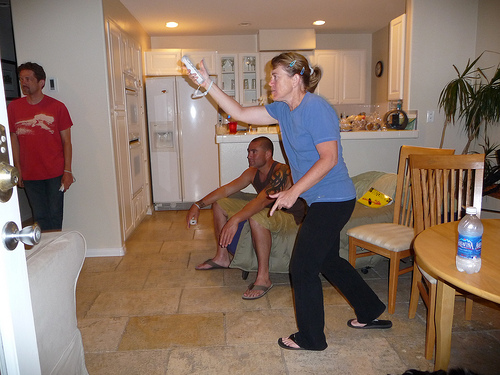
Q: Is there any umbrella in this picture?
A: No, there are no umbrellas.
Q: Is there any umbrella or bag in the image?
A: No, there are no umbrellas or bags.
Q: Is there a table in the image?
A: Yes, there is a table.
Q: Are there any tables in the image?
A: Yes, there is a table.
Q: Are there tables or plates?
A: Yes, there is a table.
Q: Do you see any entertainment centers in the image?
A: No, there are no entertainment centers.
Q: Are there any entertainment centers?
A: No, there are no entertainment centers.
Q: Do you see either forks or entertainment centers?
A: No, there are no entertainment centers or forks.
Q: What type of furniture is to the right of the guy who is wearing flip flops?
A: The piece of furniture is a table.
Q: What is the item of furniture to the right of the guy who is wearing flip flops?
A: The piece of furniture is a table.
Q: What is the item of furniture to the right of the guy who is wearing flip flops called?
A: The piece of furniture is a table.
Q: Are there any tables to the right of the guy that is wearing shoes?
A: Yes, there is a table to the right of the guy.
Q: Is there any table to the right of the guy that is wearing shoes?
A: Yes, there is a table to the right of the guy.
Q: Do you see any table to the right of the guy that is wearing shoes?
A: Yes, there is a table to the right of the guy.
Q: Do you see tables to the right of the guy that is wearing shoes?
A: Yes, there is a table to the right of the guy.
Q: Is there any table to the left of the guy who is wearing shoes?
A: No, the table is to the right of the guy.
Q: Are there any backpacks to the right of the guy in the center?
A: No, there is a table to the right of the guy.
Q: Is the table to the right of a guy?
A: Yes, the table is to the right of a guy.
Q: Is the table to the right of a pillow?
A: No, the table is to the right of a guy.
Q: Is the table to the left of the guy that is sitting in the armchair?
A: No, the table is to the right of the guy.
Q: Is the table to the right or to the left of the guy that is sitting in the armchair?
A: The table is to the right of the guy.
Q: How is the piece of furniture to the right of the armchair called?
A: The piece of furniture is a table.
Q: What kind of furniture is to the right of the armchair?
A: The piece of furniture is a table.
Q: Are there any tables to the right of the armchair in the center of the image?
A: Yes, there is a table to the right of the armchair.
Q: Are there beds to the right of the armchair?
A: No, there is a table to the right of the armchair.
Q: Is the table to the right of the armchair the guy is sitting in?
A: Yes, the table is to the right of the armchair.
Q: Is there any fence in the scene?
A: No, there are no fences.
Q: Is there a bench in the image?
A: No, there are no benches.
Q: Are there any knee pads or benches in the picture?
A: No, there are no benches or knee pads.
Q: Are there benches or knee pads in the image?
A: No, there are no benches or knee pads.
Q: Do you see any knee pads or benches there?
A: No, there are no benches or knee pads.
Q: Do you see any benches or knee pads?
A: No, there are no benches or knee pads.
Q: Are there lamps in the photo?
A: No, there are no lamps.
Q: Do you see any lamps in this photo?
A: No, there are no lamps.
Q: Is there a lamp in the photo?
A: No, there are no lamps.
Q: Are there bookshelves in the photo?
A: No, there are no bookshelves.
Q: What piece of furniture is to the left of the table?
A: The piece of furniture is an armchair.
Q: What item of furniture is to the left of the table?
A: The piece of furniture is an armchair.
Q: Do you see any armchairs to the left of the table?
A: Yes, there is an armchair to the left of the table.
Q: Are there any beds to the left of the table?
A: No, there is an armchair to the left of the table.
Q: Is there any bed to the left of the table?
A: No, there is an armchair to the left of the table.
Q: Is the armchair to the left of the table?
A: Yes, the armchair is to the left of the table.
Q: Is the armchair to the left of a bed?
A: No, the armchair is to the left of the table.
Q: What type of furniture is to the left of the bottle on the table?
A: The piece of furniture is an armchair.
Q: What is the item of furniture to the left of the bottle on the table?
A: The piece of furniture is an armchair.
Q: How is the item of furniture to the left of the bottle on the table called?
A: The piece of furniture is an armchair.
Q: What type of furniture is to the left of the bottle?
A: The piece of furniture is an armchair.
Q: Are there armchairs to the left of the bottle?
A: Yes, there is an armchair to the left of the bottle.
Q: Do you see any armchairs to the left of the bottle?
A: Yes, there is an armchair to the left of the bottle.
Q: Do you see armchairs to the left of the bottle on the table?
A: Yes, there is an armchair to the left of the bottle.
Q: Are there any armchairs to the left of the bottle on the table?
A: Yes, there is an armchair to the left of the bottle.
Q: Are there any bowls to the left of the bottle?
A: No, there is an armchair to the left of the bottle.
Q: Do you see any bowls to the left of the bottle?
A: No, there is an armchair to the left of the bottle.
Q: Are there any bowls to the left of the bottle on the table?
A: No, there is an armchair to the left of the bottle.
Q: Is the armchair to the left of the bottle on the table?
A: Yes, the armchair is to the left of the bottle.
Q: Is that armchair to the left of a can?
A: No, the armchair is to the left of the bottle.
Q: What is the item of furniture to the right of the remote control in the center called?
A: The piece of furniture is an armchair.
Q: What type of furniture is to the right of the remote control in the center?
A: The piece of furniture is an armchair.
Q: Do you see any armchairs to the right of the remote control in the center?
A: Yes, there is an armchair to the right of the remote control.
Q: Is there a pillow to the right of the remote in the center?
A: No, there is an armchair to the right of the remote control.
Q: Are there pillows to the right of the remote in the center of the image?
A: No, there is an armchair to the right of the remote control.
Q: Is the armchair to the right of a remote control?
A: Yes, the armchair is to the right of a remote control.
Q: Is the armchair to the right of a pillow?
A: No, the armchair is to the right of a remote control.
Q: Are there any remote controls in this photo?
A: Yes, there is a remote control.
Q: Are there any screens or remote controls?
A: Yes, there is a remote control.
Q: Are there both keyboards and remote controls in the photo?
A: No, there is a remote control but no keyboards.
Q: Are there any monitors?
A: No, there are no monitors.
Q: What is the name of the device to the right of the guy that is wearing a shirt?
A: The device is a remote control.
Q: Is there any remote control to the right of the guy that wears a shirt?
A: Yes, there is a remote control to the right of the guy.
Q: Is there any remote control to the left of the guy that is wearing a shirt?
A: No, the remote control is to the right of the guy.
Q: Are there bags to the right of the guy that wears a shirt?
A: No, there is a remote control to the right of the guy.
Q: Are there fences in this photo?
A: No, there are no fences.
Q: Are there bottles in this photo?
A: Yes, there is a bottle.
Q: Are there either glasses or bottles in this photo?
A: Yes, there is a bottle.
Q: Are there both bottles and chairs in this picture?
A: Yes, there are both a bottle and a chair.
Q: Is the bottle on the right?
A: Yes, the bottle is on the right of the image.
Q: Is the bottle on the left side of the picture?
A: No, the bottle is on the right of the image.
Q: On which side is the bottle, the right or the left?
A: The bottle is on the right of the image.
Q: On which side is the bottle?
A: The bottle is on the right of the image.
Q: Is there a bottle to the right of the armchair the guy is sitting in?
A: Yes, there is a bottle to the right of the armchair.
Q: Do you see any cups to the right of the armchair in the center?
A: No, there is a bottle to the right of the armchair.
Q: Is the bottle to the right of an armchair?
A: Yes, the bottle is to the right of an armchair.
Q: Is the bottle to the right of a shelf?
A: No, the bottle is to the right of an armchair.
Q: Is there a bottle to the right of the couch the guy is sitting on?
A: Yes, there is a bottle to the right of the couch.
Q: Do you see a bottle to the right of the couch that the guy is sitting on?
A: Yes, there is a bottle to the right of the couch.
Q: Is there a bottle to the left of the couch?
A: No, the bottle is to the right of the couch.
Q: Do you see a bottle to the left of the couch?
A: No, the bottle is to the right of the couch.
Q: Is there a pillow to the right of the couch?
A: No, there is a bottle to the right of the couch.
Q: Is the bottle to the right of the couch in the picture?
A: Yes, the bottle is to the right of the couch.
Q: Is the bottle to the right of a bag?
A: No, the bottle is to the right of the couch.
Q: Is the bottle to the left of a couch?
A: No, the bottle is to the right of a couch.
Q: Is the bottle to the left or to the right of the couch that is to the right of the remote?
A: The bottle is to the right of the couch.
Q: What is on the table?
A: The bottle is on the table.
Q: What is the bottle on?
A: The bottle is on the table.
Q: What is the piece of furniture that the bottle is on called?
A: The piece of furniture is a table.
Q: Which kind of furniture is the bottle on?
A: The bottle is on the table.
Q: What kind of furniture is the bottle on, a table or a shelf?
A: The bottle is on a table.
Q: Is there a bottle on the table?
A: Yes, there is a bottle on the table.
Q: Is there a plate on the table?
A: No, there is a bottle on the table.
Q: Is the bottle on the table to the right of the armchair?
A: Yes, the bottle is on the table.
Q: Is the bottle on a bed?
A: No, the bottle is on the table.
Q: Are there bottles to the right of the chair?
A: Yes, there is a bottle to the right of the chair.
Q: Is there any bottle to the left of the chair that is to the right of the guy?
A: No, the bottle is to the right of the chair.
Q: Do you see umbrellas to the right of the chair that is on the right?
A: No, there is a bottle to the right of the chair.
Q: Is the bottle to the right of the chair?
A: Yes, the bottle is to the right of the chair.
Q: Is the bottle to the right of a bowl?
A: No, the bottle is to the right of the chair.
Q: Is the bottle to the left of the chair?
A: No, the bottle is to the right of the chair.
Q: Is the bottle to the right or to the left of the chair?
A: The bottle is to the right of the chair.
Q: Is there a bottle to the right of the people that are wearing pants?
A: Yes, there is a bottle to the right of the people.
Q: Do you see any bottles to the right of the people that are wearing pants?
A: Yes, there is a bottle to the right of the people.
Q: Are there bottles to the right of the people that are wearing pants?
A: Yes, there is a bottle to the right of the people.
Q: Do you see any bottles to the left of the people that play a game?
A: No, the bottle is to the right of the people.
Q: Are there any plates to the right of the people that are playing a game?
A: No, there is a bottle to the right of the people.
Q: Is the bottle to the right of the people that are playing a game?
A: Yes, the bottle is to the right of the people.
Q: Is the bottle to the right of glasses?
A: No, the bottle is to the right of the people.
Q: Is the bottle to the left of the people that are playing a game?
A: No, the bottle is to the right of the people.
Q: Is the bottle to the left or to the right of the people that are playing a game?
A: The bottle is to the right of the people.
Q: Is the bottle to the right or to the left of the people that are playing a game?
A: The bottle is to the right of the people.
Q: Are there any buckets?
A: No, there are no buckets.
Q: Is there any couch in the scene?
A: Yes, there is a couch.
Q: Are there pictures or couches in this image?
A: Yes, there is a couch.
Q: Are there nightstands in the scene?
A: No, there are no nightstands.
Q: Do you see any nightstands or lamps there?
A: No, there are no nightstands or lamps.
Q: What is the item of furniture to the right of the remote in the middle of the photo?
A: The piece of furniture is a couch.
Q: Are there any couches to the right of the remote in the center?
A: Yes, there is a couch to the right of the remote.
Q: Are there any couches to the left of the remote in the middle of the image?
A: No, the couch is to the right of the remote.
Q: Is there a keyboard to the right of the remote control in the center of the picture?
A: No, there is a couch to the right of the remote control.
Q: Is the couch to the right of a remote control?
A: Yes, the couch is to the right of a remote control.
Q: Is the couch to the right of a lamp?
A: No, the couch is to the right of a remote control.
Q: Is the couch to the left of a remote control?
A: No, the couch is to the right of a remote control.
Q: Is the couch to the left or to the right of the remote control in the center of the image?
A: The couch is to the right of the remote.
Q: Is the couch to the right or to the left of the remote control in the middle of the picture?
A: The couch is to the right of the remote.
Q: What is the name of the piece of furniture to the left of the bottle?
A: The piece of furniture is a couch.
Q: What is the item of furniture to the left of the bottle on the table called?
A: The piece of furniture is a couch.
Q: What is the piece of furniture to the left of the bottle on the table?
A: The piece of furniture is a couch.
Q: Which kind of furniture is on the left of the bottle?
A: The piece of furniture is a couch.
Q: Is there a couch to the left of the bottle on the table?
A: Yes, there is a couch to the left of the bottle.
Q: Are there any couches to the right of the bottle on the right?
A: No, the couch is to the left of the bottle.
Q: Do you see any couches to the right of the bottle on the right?
A: No, the couch is to the left of the bottle.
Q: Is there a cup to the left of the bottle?
A: No, there is a couch to the left of the bottle.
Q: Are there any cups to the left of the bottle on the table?
A: No, there is a couch to the left of the bottle.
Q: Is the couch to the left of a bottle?
A: Yes, the couch is to the left of a bottle.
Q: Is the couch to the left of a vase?
A: No, the couch is to the left of a bottle.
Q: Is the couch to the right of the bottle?
A: No, the couch is to the left of the bottle.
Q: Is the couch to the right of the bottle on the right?
A: No, the couch is to the left of the bottle.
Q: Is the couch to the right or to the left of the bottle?
A: The couch is to the left of the bottle.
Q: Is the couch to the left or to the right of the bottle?
A: The couch is to the left of the bottle.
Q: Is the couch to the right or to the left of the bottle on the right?
A: The couch is to the left of the bottle.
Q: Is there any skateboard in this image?
A: No, there are no skateboards.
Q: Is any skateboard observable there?
A: No, there are no skateboards.